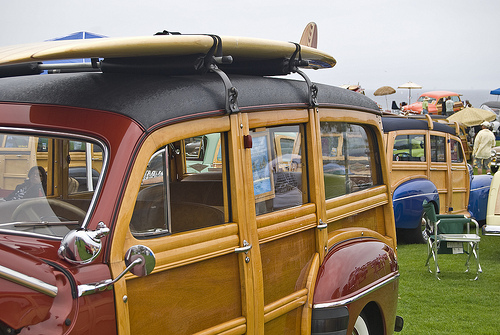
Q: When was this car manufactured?
A: Mid 1900's.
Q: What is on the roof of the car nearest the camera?
A: A surfboard.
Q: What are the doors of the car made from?
A: Wood.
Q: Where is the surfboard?
A: On roof.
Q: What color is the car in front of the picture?
A: Red and brown.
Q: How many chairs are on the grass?
A: 1.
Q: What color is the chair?
A: Green.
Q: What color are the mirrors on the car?
A: Silver.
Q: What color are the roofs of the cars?
A: Black.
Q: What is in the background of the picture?
A: Water.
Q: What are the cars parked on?
A: Grass.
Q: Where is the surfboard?
A: On top of the car.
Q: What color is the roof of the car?
A: Black.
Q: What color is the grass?
A: Green.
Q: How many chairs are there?
A: 1.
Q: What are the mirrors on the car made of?
A: Chrome.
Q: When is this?
A: Day time.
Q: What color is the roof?
A: Black.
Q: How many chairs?
A: 1.